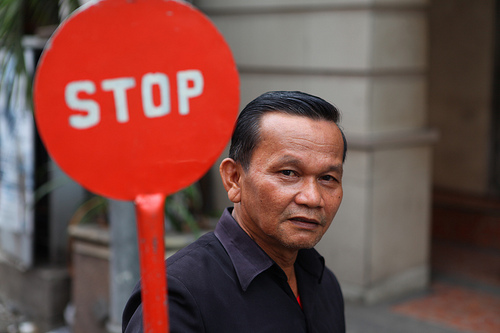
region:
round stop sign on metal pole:
[24, 1, 255, 210]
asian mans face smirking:
[213, 65, 356, 266]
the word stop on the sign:
[58, 72, 208, 128]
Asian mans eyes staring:
[272, 155, 355, 190]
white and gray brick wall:
[364, 8, 443, 308]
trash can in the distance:
[62, 214, 119, 329]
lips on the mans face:
[278, 204, 330, 237]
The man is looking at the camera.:
[218, 89, 351, 248]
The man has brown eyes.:
[276, 159, 338, 186]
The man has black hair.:
[218, 87, 350, 252]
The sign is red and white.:
[28, 0, 243, 200]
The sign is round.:
[26, 0, 241, 198]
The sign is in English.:
[30, 4, 240, 196]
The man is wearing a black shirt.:
[125, 92, 367, 332]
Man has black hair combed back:
[221, 83, 355, 179]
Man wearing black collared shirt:
[111, 208, 387, 330]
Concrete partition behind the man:
[232, 9, 462, 296]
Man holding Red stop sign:
[15, 4, 237, 331]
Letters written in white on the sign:
[36, 53, 217, 145]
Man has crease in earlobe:
[218, 155, 250, 212]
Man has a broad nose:
[270, 178, 340, 215]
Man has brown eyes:
[270, 160, 348, 192]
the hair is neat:
[245, 95, 340, 126]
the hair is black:
[255, 95, 332, 120]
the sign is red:
[50, 20, 220, 327]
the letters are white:
[60, 70, 205, 130]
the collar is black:
[220, 210, 330, 291]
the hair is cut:
[250, 86, 347, 128]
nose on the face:
[299, 182, 323, 207]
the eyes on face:
[276, 164, 338, 186]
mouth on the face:
[284, 207, 318, 244]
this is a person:
[113, 92, 348, 329]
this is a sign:
[20, 0, 241, 217]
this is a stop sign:
[29, 0, 245, 220]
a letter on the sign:
[48, 73, 121, 150]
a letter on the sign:
[97, 71, 137, 124]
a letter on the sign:
[139, 68, 174, 123]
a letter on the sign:
[175, 62, 209, 123]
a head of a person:
[208, 80, 357, 257]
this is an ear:
[215, 149, 245, 219]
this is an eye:
[273, 160, 305, 196]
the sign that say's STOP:
[32, 0, 238, 200]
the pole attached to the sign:
[132, 190, 170, 331]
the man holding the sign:
[120, 90, 345, 330]